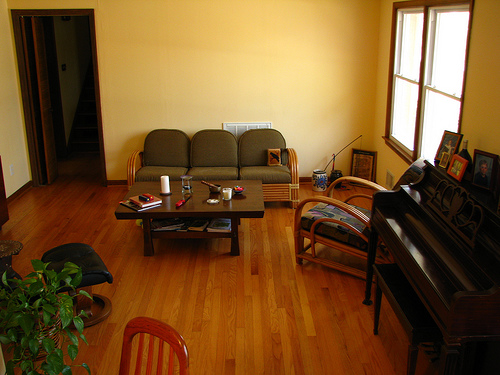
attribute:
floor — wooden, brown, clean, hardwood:
[4, 174, 443, 372]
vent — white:
[219, 120, 273, 129]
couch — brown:
[127, 127, 300, 189]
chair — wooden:
[119, 314, 192, 373]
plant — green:
[3, 255, 93, 372]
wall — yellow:
[375, 2, 495, 192]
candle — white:
[159, 173, 170, 193]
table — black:
[114, 178, 264, 216]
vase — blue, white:
[309, 169, 329, 192]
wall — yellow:
[92, 5, 378, 178]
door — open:
[9, 3, 112, 190]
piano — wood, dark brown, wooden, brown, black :
[358, 151, 496, 369]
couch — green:
[119, 124, 302, 214]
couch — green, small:
[121, 123, 299, 221]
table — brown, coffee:
[111, 174, 266, 257]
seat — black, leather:
[39, 241, 115, 330]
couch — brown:
[127, 126, 297, 216]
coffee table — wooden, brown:
[113, 172, 268, 258]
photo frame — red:
[442, 149, 475, 184]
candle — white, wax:
[154, 171, 175, 197]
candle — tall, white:
[158, 171, 173, 197]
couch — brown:
[123, 126, 301, 209]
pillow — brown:
[264, 145, 284, 168]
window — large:
[383, 3, 474, 176]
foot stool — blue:
[38, 241, 114, 331]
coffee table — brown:
[108, 179, 268, 257]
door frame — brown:
[5, 1, 113, 184]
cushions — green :
[138, 125, 294, 187]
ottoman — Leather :
[39, 229, 126, 329]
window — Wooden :
[381, 10, 471, 178]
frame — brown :
[385, 3, 474, 173]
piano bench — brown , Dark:
[365, 256, 455, 373]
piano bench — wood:
[351, 239, 461, 373]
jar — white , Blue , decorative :
[307, 165, 329, 194]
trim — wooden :
[120, 149, 301, 206]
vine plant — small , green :
[0, 257, 91, 373]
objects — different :
[119, 166, 243, 216]